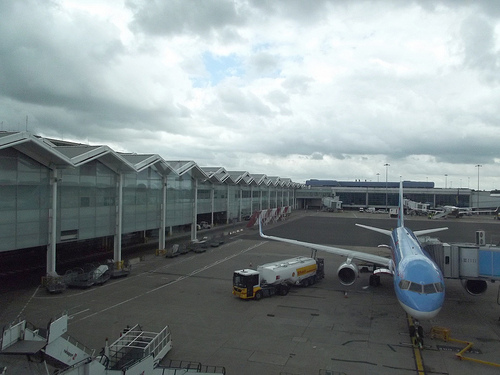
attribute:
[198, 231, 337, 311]
truck — fueling, yellow, white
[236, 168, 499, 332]
airplane — fueling, blue, white, light blue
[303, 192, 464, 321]
plane — refueling, blue, parked, large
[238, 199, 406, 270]
wing — white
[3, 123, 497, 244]
airport — commercial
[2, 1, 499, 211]
sky — dark, cloudy, white, light blue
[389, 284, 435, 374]
line — yellow